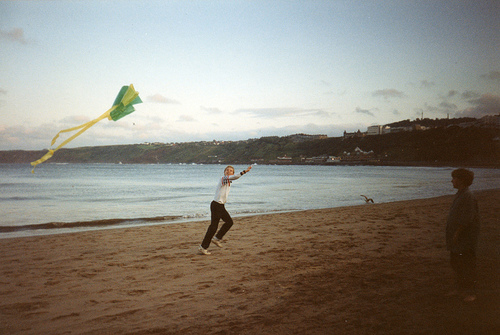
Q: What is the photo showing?
A: It is showing a beach.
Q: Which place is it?
A: It is a beach.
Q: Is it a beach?
A: Yes, it is a beach.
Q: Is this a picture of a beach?
A: Yes, it is showing a beach.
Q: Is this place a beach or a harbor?
A: It is a beach.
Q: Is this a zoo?
A: No, it is a beach.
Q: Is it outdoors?
A: Yes, it is outdoors.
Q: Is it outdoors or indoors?
A: It is outdoors.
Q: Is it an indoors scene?
A: No, it is outdoors.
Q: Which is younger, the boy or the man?
A: The boy is younger than the man.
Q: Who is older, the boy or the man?
A: The man is older than the boy.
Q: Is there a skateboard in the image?
A: No, there are no skateboards.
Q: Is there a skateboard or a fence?
A: No, there are no skateboards or fences.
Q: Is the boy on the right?
A: Yes, the boy is on the right of the image.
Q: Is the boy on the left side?
A: No, the boy is on the right of the image.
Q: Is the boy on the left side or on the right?
A: The boy is on the right of the image.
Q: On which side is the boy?
A: The boy is on the right of the image.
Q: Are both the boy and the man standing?
A: Yes, both the boy and the man are standing.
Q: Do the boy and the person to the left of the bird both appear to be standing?
A: Yes, both the boy and the man are standing.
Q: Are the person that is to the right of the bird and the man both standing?
A: Yes, both the boy and the man are standing.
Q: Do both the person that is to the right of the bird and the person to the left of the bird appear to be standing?
A: Yes, both the boy and the man are standing.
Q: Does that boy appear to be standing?
A: Yes, the boy is standing.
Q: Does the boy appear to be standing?
A: Yes, the boy is standing.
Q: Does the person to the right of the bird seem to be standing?
A: Yes, the boy is standing.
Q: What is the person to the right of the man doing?
A: The boy is standing.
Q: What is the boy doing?
A: The boy is standing.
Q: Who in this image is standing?
A: The boy is standing.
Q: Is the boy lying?
A: No, the boy is standing.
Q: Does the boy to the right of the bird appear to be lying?
A: No, the boy is standing.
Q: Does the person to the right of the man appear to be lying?
A: No, the boy is standing.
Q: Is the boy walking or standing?
A: The boy is standing.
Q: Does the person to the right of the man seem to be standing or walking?
A: The boy is standing.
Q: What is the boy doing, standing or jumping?
A: The boy is standing.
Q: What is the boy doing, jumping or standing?
A: The boy is standing.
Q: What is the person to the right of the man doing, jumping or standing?
A: The boy is standing.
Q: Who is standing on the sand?
A: The boy is standing on the sand.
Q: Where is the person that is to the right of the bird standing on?
A: The boy is standing on the sand.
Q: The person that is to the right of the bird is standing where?
A: The boy is standing on the sand.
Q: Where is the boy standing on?
A: The boy is standing on the sand.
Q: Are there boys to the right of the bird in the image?
A: Yes, there is a boy to the right of the bird.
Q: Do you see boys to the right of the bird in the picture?
A: Yes, there is a boy to the right of the bird.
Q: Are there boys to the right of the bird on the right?
A: Yes, there is a boy to the right of the bird.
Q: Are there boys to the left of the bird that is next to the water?
A: No, the boy is to the right of the bird.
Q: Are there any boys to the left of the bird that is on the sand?
A: No, the boy is to the right of the bird.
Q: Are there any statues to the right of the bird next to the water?
A: No, there is a boy to the right of the bird.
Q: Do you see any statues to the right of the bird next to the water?
A: No, there is a boy to the right of the bird.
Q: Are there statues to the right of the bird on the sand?
A: No, there is a boy to the right of the bird.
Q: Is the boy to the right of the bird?
A: Yes, the boy is to the right of the bird.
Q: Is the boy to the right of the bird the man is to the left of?
A: Yes, the boy is to the right of the bird.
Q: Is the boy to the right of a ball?
A: No, the boy is to the right of the bird.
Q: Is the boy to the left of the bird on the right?
A: No, the boy is to the right of the bird.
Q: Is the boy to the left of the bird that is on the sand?
A: No, the boy is to the right of the bird.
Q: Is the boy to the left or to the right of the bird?
A: The boy is to the right of the bird.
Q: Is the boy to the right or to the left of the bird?
A: The boy is to the right of the bird.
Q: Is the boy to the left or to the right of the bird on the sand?
A: The boy is to the right of the bird.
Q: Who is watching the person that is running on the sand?
A: The boy is watching the man.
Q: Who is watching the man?
A: The boy is watching the man.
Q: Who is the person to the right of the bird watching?
A: The boy is watching the man.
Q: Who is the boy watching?
A: The boy is watching the man.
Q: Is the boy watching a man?
A: Yes, the boy is watching a man.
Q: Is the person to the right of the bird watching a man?
A: Yes, the boy is watching a man.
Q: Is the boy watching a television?
A: No, the boy is watching a man.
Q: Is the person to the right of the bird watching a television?
A: No, the boy is watching a man.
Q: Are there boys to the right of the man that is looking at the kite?
A: Yes, there is a boy to the right of the man.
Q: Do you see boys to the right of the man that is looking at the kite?
A: Yes, there is a boy to the right of the man.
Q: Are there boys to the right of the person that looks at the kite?
A: Yes, there is a boy to the right of the man.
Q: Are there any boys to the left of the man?
A: No, the boy is to the right of the man.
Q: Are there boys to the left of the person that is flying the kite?
A: No, the boy is to the right of the man.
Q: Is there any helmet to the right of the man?
A: No, there is a boy to the right of the man.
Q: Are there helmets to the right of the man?
A: No, there is a boy to the right of the man.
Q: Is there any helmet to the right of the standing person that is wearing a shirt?
A: No, there is a boy to the right of the man.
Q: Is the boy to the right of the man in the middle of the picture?
A: Yes, the boy is to the right of the man.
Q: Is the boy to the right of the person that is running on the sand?
A: Yes, the boy is to the right of the man.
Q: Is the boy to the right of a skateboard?
A: No, the boy is to the right of the man.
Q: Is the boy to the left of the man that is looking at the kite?
A: No, the boy is to the right of the man.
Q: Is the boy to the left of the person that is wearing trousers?
A: No, the boy is to the right of the man.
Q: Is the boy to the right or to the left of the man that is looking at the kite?
A: The boy is to the right of the man.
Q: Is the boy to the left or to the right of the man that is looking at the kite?
A: The boy is to the right of the man.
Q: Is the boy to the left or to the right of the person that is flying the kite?
A: The boy is to the right of the man.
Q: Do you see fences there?
A: No, there are no fences.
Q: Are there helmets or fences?
A: No, there are no fences or helmets.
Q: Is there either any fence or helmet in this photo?
A: No, there are no fences or helmets.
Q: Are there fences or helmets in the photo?
A: No, there are no fences or helmets.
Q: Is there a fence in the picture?
A: No, there are no fences.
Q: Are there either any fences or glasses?
A: No, there are no fences or glasses.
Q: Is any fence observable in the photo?
A: No, there are no fences.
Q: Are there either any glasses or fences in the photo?
A: No, there are no fences or glasses.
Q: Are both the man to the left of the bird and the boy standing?
A: Yes, both the man and the boy are standing.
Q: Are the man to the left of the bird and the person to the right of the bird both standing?
A: Yes, both the man and the boy are standing.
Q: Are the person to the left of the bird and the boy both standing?
A: Yes, both the man and the boy are standing.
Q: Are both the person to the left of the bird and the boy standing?
A: Yes, both the man and the boy are standing.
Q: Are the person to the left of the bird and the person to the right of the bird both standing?
A: Yes, both the man and the boy are standing.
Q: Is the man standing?
A: Yes, the man is standing.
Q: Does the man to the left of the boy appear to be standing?
A: Yes, the man is standing.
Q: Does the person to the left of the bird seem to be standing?
A: Yes, the man is standing.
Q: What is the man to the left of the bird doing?
A: The man is standing.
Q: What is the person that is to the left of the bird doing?
A: The man is standing.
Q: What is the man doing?
A: The man is standing.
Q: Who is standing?
A: The man is standing.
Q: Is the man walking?
A: No, the man is standing.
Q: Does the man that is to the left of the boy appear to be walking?
A: No, the man is standing.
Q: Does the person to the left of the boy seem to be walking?
A: No, the man is standing.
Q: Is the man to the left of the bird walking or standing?
A: The man is standing.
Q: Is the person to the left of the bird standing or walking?
A: The man is standing.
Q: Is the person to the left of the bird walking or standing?
A: The man is standing.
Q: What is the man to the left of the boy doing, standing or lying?
A: The man is standing.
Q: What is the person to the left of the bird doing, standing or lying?
A: The man is standing.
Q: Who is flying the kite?
A: The man is flying the kite.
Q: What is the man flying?
A: The man is flying the kite.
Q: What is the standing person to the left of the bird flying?
A: The man is flying the kite.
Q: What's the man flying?
A: The man is flying the kite.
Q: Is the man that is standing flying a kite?
A: Yes, the man is flying a kite.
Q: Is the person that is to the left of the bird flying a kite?
A: Yes, the man is flying a kite.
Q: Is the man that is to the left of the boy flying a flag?
A: No, the man is flying a kite.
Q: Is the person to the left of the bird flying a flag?
A: No, the man is flying a kite.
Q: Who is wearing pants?
A: The man is wearing pants.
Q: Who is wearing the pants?
A: The man is wearing pants.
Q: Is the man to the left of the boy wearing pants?
A: Yes, the man is wearing pants.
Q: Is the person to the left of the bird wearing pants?
A: Yes, the man is wearing pants.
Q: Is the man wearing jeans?
A: No, the man is wearing pants.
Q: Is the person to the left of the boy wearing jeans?
A: No, the man is wearing pants.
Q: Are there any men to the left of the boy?
A: Yes, there is a man to the left of the boy.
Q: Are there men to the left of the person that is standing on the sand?
A: Yes, there is a man to the left of the boy.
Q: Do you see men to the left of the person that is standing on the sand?
A: Yes, there is a man to the left of the boy.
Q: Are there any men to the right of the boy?
A: No, the man is to the left of the boy.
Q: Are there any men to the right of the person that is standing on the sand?
A: No, the man is to the left of the boy.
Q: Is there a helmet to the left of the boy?
A: No, there is a man to the left of the boy.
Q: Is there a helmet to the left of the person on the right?
A: No, there is a man to the left of the boy.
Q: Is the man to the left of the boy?
A: Yes, the man is to the left of the boy.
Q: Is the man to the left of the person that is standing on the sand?
A: Yes, the man is to the left of the boy.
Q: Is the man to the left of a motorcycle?
A: No, the man is to the left of the boy.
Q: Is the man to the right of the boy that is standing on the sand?
A: No, the man is to the left of the boy.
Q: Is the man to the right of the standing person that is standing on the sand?
A: No, the man is to the left of the boy.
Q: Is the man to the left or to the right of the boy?
A: The man is to the left of the boy.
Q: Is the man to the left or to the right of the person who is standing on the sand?
A: The man is to the left of the boy.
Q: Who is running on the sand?
A: The man is running on the sand.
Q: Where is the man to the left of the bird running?
A: The man is running on the sand.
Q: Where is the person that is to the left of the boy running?
A: The man is running on the sand.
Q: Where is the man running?
A: The man is running on the sand.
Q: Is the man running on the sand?
A: Yes, the man is running on the sand.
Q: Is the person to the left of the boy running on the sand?
A: Yes, the man is running on the sand.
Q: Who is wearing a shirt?
A: The man is wearing a shirt.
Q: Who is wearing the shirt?
A: The man is wearing a shirt.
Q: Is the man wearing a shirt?
A: Yes, the man is wearing a shirt.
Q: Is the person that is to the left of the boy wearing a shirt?
A: Yes, the man is wearing a shirt.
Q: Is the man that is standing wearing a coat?
A: No, the man is wearing a shirt.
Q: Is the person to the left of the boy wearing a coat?
A: No, the man is wearing a shirt.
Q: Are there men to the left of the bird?
A: Yes, there is a man to the left of the bird.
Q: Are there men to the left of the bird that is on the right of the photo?
A: Yes, there is a man to the left of the bird.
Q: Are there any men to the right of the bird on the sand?
A: No, the man is to the left of the bird.